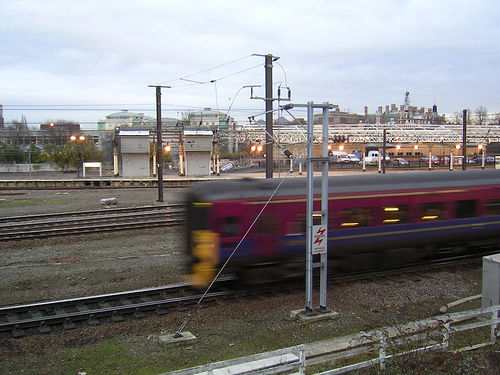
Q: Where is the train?
A: On the tracks.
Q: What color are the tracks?
A: Brown.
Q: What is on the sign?
A: A warning.